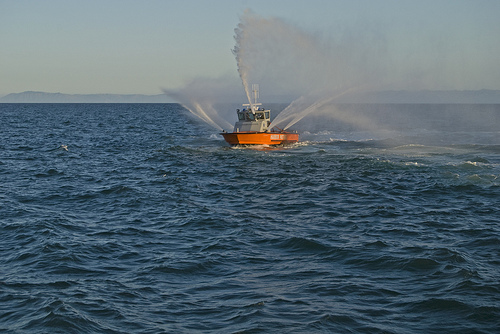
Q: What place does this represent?
A: It represents the ocean.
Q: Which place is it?
A: It is an ocean.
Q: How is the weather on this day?
A: It is clear.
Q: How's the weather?
A: It is clear.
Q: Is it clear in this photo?
A: Yes, it is clear.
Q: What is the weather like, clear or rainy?
A: It is clear.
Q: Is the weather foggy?
A: No, it is clear.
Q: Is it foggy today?
A: No, it is clear.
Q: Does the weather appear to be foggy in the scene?
A: No, it is clear.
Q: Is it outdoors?
A: Yes, it is outdoors.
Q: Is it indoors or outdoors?
A: It is outdoors.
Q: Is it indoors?
A: No, it is outdoors.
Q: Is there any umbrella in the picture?
A: No, there are no umbrellas.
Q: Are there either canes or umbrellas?
A: No, there are no umbrellas or canes.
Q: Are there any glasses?
A: No, there are no glasses.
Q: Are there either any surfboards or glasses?
A: No, there are no glasses or surfboards.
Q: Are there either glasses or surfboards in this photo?
A: No, there are no glasses or surfboards.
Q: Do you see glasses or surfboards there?
A: No, there are no glasses or surfboards.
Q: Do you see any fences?
A: No, there are no fences.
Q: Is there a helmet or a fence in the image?
A: No, there are no fences or helmets.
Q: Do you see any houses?
A: No, there are no houses.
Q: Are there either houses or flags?
A: No, there are no houses or flags.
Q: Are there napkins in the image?
A: No, there are no napkins.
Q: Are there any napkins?
A: No, there are no napkins.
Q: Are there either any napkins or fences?
A: No, there are no napkins or fences.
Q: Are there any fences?
A: No, there are no fences.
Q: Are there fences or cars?
A: No, there are no fences or cars.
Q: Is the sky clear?
A: Yes, the sky is clear.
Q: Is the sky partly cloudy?
A: No, the sky is clear.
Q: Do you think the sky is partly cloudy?
A: No, the sky is clear.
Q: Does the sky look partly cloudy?
A: No, the sky is clear.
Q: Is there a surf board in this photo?
A: No, there are no surfboards.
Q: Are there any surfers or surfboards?
A: No, there are no surfboards or surfers.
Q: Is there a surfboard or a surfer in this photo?
A: No, there are no surfboards or surfers.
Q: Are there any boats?
A: Yes, there is a boat.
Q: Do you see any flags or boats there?
A: Yes, there is a boat.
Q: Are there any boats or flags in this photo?
A: Yes, there is a boat.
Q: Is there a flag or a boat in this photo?
A: Yes, there is a boat.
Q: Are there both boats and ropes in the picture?
A: No, there is a boat but no ropes.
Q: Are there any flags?
A: No, there are no flags.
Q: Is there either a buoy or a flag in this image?
A: No, there are no flags or buoys.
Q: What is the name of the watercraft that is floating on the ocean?
A: The watercraft is a boat.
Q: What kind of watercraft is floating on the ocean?
A: The watercraft is a boat.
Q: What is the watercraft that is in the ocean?
A: The watercraft is a boat.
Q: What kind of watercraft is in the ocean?
A: The watercraft is a boat.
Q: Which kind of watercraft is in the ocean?
A: The watercraft is a boat.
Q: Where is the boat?
A: The boat is in the ocean.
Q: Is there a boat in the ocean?
A: Yes, there is a boat in the ocean.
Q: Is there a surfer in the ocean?
A: No, there is a boat in the ocean.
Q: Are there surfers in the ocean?
A: No, there is a boat in the ocean.